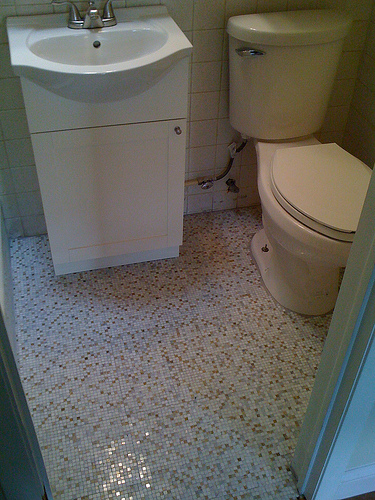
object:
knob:
[173, 124, 183, 139]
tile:
[11, 340, 128, 442]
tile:
[174, 206, 271, 316]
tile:
[8, 236, 111, 354]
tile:
[93, 263, 193, 341]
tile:
[107, 322, 224, 419]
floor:
[8, 207, 360, 499]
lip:
[30, 42, 178, 83]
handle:
[235, 50, 264, 58]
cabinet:
[27, 119, 190, 266]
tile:
[192, 29, 222, 65]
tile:
[190, 63, 222, 95]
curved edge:
[11, 43, 193, 87]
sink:
[26, 26, 170, 66]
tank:
[225, 11, 357, 145]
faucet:
[79, 0, 103, 32]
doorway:
[50, 452, 303, 499]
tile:
[3, 136, 34, 171]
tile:
[187, 147, 216, 175]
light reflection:
[96, 433, 153, 500]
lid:
[225, 9, 357, 47]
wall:
[0, 1, 374, 239]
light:
[97, 433, 156, 499]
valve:
[198, 178, 213, 191]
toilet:
[225, 10, 373, 317]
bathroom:
[0, 0, 374, 499]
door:
[29, 117, 189, 268]